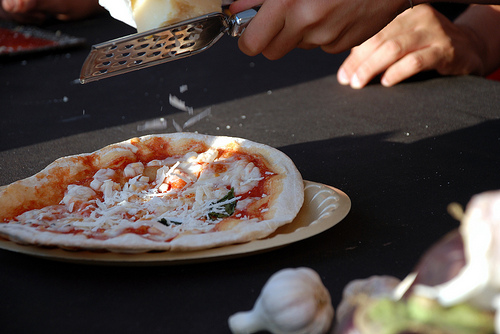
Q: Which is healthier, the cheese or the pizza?
A: The cheese is healthier than the pizza.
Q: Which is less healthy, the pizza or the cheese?
A: The pizza is less healthy than the cheese.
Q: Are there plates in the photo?
A: Yes, there is a plate.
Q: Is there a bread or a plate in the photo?
A: Yes, there is a plate.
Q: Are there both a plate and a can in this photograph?
A: No, there is a plate but no cans.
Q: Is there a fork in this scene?
A: No, there are no forks.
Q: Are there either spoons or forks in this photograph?
A: No, there are no forks or spoons.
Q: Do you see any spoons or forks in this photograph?
A: No, there are no forks or spoons.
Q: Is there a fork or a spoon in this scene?
A: No, there are no forks or spoons.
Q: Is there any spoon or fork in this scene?
A: No, there are no forks or spoons.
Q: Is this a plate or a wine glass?
A: This is a plate.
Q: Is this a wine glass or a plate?
A: This is a plate.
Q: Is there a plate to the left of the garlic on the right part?
A: Yes, there is a plate to the left of the garlic.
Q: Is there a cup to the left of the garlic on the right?
A: No, there is a plate to the left of the garlic.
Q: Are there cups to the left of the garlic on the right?
A: No, there is a plate to the left of the garlic.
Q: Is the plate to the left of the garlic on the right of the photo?
A: Yes, the plate is to the left of the garlic.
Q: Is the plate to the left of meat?
A: No, the plate is to the left of the garlic.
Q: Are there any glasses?
A: No, there are no glasses.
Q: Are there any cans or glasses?
A: No, there are no glasses or cans.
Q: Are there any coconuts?
A: No, there are no coconuts.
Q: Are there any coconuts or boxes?
A: No, there are no coconuts or boxes.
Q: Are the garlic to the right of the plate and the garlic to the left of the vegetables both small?
A: Yes, both the garlic and the garlic are small.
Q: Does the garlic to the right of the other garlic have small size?
A: Yes, the garlic is small.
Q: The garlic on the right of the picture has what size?
A: The garlic is small.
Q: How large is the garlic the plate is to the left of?
A: The garlic is small.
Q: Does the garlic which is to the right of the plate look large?
A: No, the garlic is small.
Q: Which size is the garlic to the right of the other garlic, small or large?
A: The garlic is small.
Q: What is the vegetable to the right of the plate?
A: The vegetable is garlic.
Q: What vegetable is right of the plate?
A: The vegetable is garlic.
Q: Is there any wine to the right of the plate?
A: No, there is garlic to the right of the plate.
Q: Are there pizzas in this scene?
A: Yes, there is a pizza.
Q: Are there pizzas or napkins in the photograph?
A: Yes, there is a pizza.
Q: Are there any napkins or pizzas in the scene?
A: Yes, there is a pizza.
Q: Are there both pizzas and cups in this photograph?
A: No, there is a pizza but no cups.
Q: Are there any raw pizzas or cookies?
A: Yes, there is a raw pizza.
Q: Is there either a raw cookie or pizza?
A: Yes, there is a raw pizza.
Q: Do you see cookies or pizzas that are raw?
A: Yes, the pizza is raw.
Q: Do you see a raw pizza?
A: Yes, there is a raw pizza.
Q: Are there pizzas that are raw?
A: Yes, there is a pizza that is raw.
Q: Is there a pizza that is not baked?
A: Yes, there is a raw pizza.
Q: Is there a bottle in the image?
A: No, there are no bottles.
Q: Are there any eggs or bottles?
A: No, there are no bottles or eggs.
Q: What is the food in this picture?
A: The food is a pizza.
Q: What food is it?
A: The food is a pizza.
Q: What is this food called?
A: This is a pizza.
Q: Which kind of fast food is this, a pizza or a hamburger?
A: This is a pizza.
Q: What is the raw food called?
A: The food is a pizza.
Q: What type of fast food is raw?
A: The fast food is a pizza.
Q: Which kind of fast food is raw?
A: The fast food is a pizza.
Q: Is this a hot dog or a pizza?
A: This is a pizza.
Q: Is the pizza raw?
A: Yes, the pizza is raw.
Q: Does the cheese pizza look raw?
A: Yes, the pizza is raw.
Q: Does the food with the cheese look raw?
A: Yes, the pizza is raw.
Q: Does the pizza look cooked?
A: No, the pizza is raw.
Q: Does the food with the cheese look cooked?
A: No, the pizza is raw.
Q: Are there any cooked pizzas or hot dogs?
A: No, there is a pizza but it is raw.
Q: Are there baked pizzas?
A: No, there is a pizza but it is raw.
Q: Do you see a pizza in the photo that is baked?
A: No, there is a pizza but it is raw.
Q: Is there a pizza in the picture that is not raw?
A: No, there is a pizza but it is raw.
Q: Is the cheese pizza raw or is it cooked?
A: The pizza is raw.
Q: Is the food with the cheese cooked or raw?
A: The pizza is raw.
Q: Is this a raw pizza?
A: Yes, this is a raw pizza.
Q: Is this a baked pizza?
A: No, this is a raw pizza.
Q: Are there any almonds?
A: No, there are no almonds.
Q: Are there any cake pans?
A: No, there are no cake pans.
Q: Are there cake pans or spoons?
A: No, there are no cake pans or spoons.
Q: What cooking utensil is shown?
A: The cooking utensil is a grater.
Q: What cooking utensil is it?
A: The cooking utensil is a grater.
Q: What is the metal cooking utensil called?
A: The cooking utensil is a grater.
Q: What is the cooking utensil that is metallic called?
A: The cooking utensil is a grater.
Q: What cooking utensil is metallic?
A: The cooking utensil is a grater.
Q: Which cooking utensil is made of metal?
A: The cooking utensil is a grater.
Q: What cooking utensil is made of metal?
A: The cooking utensil is a grater.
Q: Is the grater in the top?
A: Yes, the grater is in the top of the image.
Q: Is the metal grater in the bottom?
A: No, the grater is in the top of the image.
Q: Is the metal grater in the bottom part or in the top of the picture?
A: The grater is in the top of the image.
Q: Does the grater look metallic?
A: Yes, the grater is metallic.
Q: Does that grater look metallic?
A: Yes, the grater is metallic.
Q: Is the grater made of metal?
A: Yes, the grater is made of metal.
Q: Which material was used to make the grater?
A: The grater is made of metal.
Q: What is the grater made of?
A: The grater is made of metal.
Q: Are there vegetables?
A: Yes, there are vegetables.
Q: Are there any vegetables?
A: Yes, there are vegetables.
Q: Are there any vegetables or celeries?
A: Yes, there are vegetables.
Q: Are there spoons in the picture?
A: No, there are no spoons.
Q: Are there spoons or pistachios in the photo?
A: No, there are no spoons or pistachios.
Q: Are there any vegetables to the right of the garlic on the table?
A: Yes, there are vegetables to the right of the garlic.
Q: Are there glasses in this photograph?
A: No, there are no glasses.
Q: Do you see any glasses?
A: No, there are no glasses.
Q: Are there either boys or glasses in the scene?
A: No, there are no glasses or boys.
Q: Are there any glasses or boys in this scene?
A: No, there are no glasses or boys.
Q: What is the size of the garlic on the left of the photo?
A: The garlic is small.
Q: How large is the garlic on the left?
A: The garlic is small.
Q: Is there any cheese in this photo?
A: Yes, there is cheese.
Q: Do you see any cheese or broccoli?
A: Yes, there is cheese.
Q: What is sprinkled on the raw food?
A: The cheese is sprinkled on the pizza.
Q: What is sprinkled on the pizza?
A: The cheese is sprinkled on the pizza.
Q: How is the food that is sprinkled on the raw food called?
A: The food is cheese.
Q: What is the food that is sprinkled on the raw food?
A: The food is cheese.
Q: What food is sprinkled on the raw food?
A: The food is cheese.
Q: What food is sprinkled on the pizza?
A: The food is cheese.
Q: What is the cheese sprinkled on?
A: The cheese is sprinkled on the pizza.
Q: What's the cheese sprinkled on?
A: The cheese is sprinkled on the pizza.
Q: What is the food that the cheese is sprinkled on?
A: The food is a pizza.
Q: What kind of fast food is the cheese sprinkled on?
A: The cheese is sprinkled on the pizza.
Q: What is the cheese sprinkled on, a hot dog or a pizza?
A: The cheese is sprinkled on a pizza.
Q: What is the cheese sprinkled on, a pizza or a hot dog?
A: The cheese is sprinkled on a pizza.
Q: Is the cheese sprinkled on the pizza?
A: Yes, the cheese is sprinkled on the pizza.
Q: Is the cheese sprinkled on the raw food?
A: Yes, the cheese is sprinkled on the pizza.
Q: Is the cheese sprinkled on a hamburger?
A: No, the cheese is sprinkled on the pizza.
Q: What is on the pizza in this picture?
A: The cheese is on the pizza.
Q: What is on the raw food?
A: The cheese is on the pizza.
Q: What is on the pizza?
A: The cheese is on the pizza.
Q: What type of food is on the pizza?
A: The food is cheese.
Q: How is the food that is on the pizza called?
A: The food is cheese.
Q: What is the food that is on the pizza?
A: The food is cheese.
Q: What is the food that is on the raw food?
A: The food is cheese.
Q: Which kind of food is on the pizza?
A: The food is cheese.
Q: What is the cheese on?
A: The cheese is on the pizza.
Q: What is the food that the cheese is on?
A: The food is a pizza.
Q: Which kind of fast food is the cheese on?
A: The cheese is on the pizza.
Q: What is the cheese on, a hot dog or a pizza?
A: The cheese is on a pizza.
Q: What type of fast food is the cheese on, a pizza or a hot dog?
A: The cheese is on a pizza.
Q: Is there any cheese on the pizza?
A: Yes, there is cheese on the pizza.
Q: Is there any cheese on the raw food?
A: Yes, there is cheese on the pizza.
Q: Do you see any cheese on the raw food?
A: Yes, there is cheese on the pizza.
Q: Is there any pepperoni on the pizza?
A: No, there is cheese on the pizza.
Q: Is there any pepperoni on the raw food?
A: No, there is cheese on the pizza.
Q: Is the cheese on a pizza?
A: Yes, the cheese is on a pizza.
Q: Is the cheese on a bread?
A: No, the cheese is on a pizza.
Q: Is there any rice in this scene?
A: No, there is no rice.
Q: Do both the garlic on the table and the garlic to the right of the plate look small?
A: Yes, both the garlic and the garlic are small.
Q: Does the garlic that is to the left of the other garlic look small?
A: Yes, the garlic is small.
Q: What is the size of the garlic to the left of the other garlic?
A: The garlic is small.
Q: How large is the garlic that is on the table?
A: The garlic is small.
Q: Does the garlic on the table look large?
A: No, the garlic is small.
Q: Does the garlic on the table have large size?
A: No, the garlic is small.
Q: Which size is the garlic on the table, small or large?
A: The garlic is small.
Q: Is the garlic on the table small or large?
A: The garlic is small.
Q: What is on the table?
A: The garlic is on the table.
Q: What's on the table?
A: The garlic is on the table.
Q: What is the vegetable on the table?
A: The vegetable is garlic.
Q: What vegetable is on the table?
A: The vegetable is garlic.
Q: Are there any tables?
A: Yes, there is a table.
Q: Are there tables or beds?
A: Yes, there is a table.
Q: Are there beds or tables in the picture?
A: Yes, there is a table.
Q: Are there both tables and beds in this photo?
A: No, there is a table but no beds.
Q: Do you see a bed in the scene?
A: No, there are no beds.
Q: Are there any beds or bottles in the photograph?
A: No, there are no beds or bottles.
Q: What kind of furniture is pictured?
A: The furniture is a table.